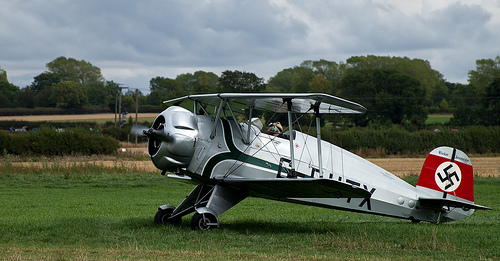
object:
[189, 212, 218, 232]
wheels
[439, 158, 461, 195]
swastika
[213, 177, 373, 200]
leftwing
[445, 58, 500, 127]
trees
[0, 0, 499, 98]
clouds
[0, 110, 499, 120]
horizon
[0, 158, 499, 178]
sand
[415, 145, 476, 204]
tailfin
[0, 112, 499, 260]
field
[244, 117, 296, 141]
cockpit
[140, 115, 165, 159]
propeller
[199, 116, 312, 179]
green stripe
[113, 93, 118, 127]
poles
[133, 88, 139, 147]
poles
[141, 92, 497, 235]
airplane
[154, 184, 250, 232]
landing gear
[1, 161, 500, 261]
grass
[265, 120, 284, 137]
pilot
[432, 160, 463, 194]
swastika symbol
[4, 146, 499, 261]
ground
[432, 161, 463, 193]
swastika